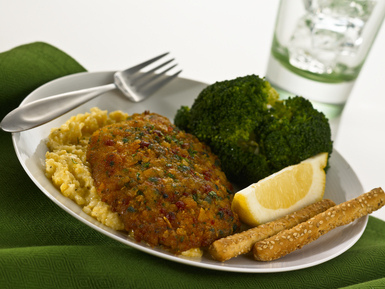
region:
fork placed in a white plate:
[1, 47, 185, 136]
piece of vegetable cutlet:
[81, 104, 247, 248]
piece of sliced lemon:
[220, 145, 334, 222]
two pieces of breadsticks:
[208, 177, 381, 273]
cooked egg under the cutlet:
[45, 104, 235, 261]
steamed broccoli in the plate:
[175, 69, 344, 183]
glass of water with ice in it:
[256, 0, 381, 90]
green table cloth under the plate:
[4, 33, 382, 286]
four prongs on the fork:
[125, 44, 191, 101]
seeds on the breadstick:
[258, 204, 353, 243]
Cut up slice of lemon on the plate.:
[257, 172, 379, 189]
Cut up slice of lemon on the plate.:
[233, 96, 259, 191]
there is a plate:
[21, 133, 42, 190]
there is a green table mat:
[14, 218, 62, 284]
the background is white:
[155, 8, 233, 50]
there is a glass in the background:
[267, 45, 319, 84]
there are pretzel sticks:
[244, 227, 343, 253]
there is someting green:
[200, 91, 303, 143]